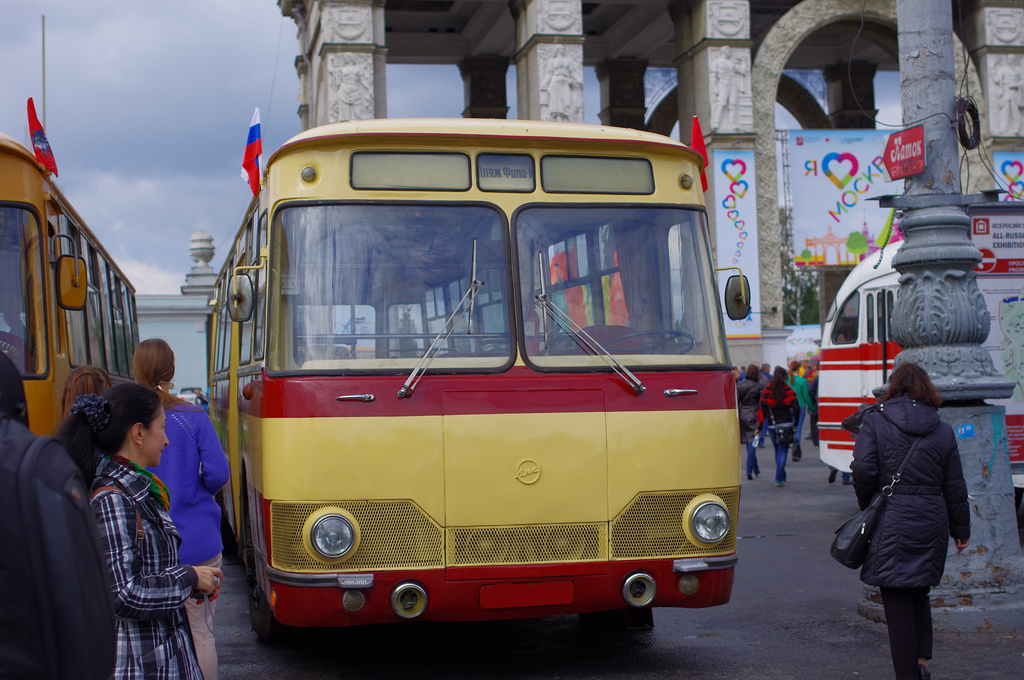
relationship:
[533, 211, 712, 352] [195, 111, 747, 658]
windshield on bus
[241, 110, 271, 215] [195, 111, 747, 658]
flag on bus